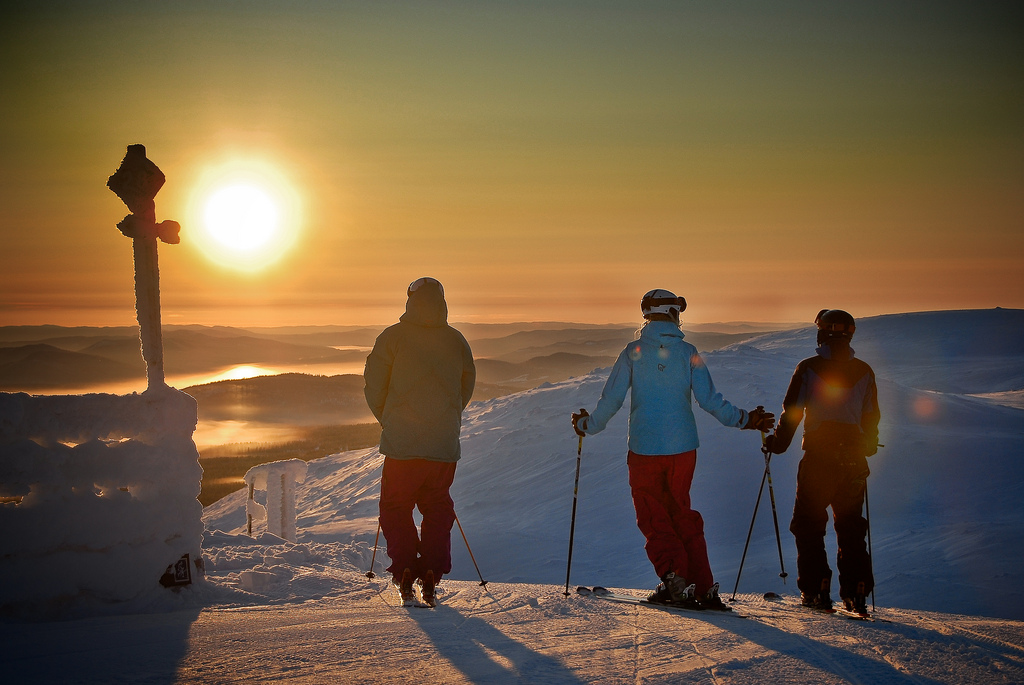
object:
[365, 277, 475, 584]
person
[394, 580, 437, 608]
skis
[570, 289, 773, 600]
person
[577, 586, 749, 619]
skis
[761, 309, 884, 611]
person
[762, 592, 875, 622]
skis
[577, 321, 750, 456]
coat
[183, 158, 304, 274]
sun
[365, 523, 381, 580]
ski pole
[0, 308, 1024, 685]
snow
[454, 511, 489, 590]
ski pole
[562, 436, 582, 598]
ski pole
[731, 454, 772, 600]
ski pole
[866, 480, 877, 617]
ski pole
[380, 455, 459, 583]
pants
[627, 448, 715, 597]
pants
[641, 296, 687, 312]
goggles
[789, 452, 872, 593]
pants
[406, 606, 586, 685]
shadow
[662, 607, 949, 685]
shadow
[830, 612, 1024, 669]
shadow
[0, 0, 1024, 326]
sky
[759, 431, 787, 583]
ski pole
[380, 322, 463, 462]
back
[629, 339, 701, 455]
back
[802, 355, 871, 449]
back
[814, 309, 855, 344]
helmet